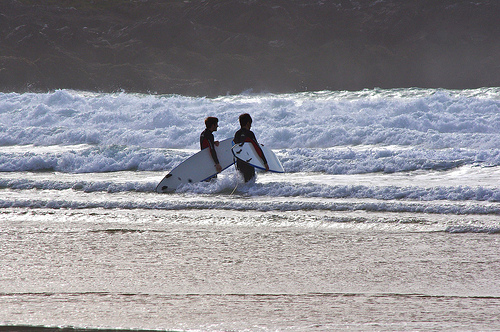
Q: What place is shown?
A: It is an ocean.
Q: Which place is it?
A: It is an ocean.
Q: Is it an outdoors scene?
A: Yes, it is outdoors.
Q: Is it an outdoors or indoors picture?
A: It is outdoors.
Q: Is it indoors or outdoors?
A: It is outdoors.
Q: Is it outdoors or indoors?
A: It is outdoors.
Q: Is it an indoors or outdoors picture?
A: It is outdoors.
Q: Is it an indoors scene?
A: No, it is outdoors.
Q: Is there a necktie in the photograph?
A: No, there are no ties.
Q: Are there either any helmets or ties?
A: No, there are no ties or helmets.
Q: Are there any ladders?
A: No, there are no ladders.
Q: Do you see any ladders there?
A: No, there are no ladders.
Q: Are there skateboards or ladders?
A: No, there are no ladders or skateboards.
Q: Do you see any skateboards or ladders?
A: No, there are no ladders or skateboards.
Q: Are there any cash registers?
A: No, there are no cash registers.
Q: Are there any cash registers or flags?
A: No, there are no cash registers or flags.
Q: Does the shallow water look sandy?
A: Yes, the water is sandy.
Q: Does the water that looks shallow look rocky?
A: No, the water is sandy.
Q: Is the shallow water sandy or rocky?
A: The water is sandy.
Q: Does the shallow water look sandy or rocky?
A: The water is sandy.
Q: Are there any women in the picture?
A: No, there are no women.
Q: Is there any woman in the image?
A: No, there are no women.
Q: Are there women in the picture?
A: No, there are no women.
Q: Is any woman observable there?
A: No, there are no women.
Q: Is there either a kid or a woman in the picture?
A: No, there are no women or children.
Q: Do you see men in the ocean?
A: Yes, there is a man in the ocean.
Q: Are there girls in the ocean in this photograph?
A: No, there is a man in the ocean.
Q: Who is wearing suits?
A: The man is wearing suits.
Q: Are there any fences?
A: No, there are no fences.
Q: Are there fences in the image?
A: No, there are no fences.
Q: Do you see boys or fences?
A: No, there are no fences or boys.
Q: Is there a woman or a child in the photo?
A: No, there are no women or children.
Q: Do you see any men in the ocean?
A: Yes, there is a man in the ocean.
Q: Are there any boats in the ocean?
A: No, there is a man in the ocean.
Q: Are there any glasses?
A: No, there are no glasses.